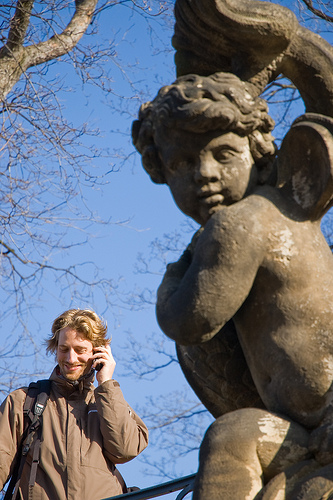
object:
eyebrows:
[59, 343, 66, 348]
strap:
[16, 382, 52, 491]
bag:
[0, 378, 52, 500]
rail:
[100, 470, 197, 499]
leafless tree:
[0, 0, 156, 314]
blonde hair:
[42, 306, 112, 363]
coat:
[0, 365, 146, 499]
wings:
[172, 0, 332, 222]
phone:
[92, 347, 104, 369]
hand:
[91, 344, 117, 382]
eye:
[214, 149, 237, 162]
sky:
[0, 1, 306, 497]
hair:
[130, 72, 278, 185]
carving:
[130, 0, 332, 499]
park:
[2, 4, 322, 490]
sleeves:
[93, 380, 148, 462]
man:
[0, 306, 147, 500]